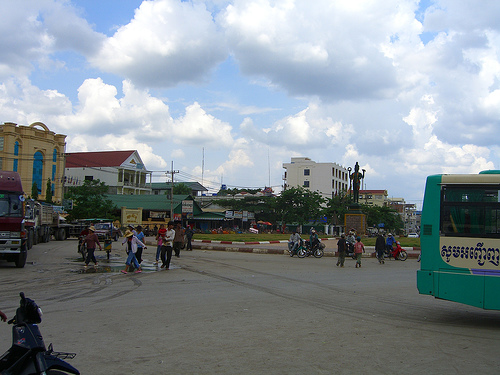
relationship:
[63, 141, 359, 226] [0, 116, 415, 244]
row of buildings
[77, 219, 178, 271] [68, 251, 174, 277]
people walking through puddle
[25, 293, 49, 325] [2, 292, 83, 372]
headlight of scooter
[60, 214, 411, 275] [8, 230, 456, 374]
people in ground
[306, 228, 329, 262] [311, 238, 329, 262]
guy on scooter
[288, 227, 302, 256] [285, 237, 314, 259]
guy on scooter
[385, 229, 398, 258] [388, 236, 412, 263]
guy on red scooter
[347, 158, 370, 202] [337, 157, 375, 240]
statue on pedestal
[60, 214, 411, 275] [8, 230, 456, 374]
people crossing road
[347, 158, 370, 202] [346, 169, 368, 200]
statue holding two poles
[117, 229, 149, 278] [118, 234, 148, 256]
person wears white jacket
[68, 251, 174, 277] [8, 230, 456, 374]
puddle in street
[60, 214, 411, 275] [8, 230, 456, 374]
people walking in street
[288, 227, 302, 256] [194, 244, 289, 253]
man sitting on curb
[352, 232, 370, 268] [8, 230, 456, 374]
boy walking across street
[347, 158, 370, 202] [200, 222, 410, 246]
statue in courtyard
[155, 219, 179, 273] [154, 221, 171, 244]
adult carrying a child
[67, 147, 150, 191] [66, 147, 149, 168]
building has red roof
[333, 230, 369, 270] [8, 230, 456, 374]
couple walking on street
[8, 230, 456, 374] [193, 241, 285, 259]
road has edge